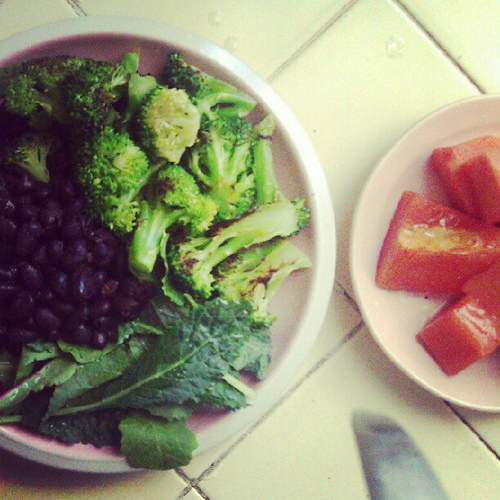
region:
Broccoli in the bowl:
[84, 78, 295, 291]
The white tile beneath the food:
[288, 405, 340, 498]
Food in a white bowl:
[4, 63, 296, 450]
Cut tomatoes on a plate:
[391, 146, 499, 347]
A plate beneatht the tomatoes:
[380, 167, 420, 187]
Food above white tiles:
[17, 28, 497, 436]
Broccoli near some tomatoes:
[143, 118, 267, 271]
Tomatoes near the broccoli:
[389, 213, 490, 353]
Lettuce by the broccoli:
[77, 330, 226, 440]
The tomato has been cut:
[381, 194, 491, 284]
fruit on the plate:
[373, 128, 498, 381]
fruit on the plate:
[365, 169, 482, 311]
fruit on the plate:
[403, 244, 495, 371]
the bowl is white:
[247, 265, 364, 427]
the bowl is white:
[211, 329, 314, 440]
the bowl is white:
[265, 177, 350, 292]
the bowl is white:
[242, 309, 329, 379]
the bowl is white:
[293, 252, 350, 383]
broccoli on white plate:
[12, 45, 274, 276]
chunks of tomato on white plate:
[340, 89, 497, 404]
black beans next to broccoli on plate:
[2, 149, 128, 343]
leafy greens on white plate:
[10, 304, 239, 457]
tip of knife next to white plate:
[343, 413, 440, 498]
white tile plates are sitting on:
[50, 44, 492, 494]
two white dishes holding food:
[12, 8, 489, 480]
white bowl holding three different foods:
[4, 20, 306, 490]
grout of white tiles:
[197, 299, 471, 499]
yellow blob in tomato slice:
[395, 219, 478, 264]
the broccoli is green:
[21, 64, 293, 343]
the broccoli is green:
[103, 140, 315, 329]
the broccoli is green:
[127, 163, 267, 300]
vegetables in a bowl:
[27, 71, 319, 461]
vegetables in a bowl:
[93, 14, 415, 492]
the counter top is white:
[272, 28, 393, 208]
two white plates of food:
[8, 21, 499, 441]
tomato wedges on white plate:
[330, 75, 497, 423]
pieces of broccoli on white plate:
[22, 60, 292, 295]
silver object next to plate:
[338, 400, 444, 497]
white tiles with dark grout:
[15, 5, 477, 489]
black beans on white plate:
[5, 167, 135, 338]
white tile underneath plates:
[2, 3, 469, 498]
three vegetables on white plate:
[11, 62, 291, 449]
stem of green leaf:
[62, 343, 227, 422]